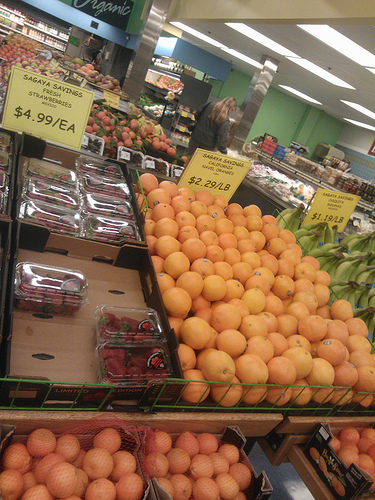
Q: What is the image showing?
A: It is showing a store.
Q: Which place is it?
A: It is a store.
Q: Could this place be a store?
A: Yes, it is a store.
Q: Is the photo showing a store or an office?
A: It is showing a store.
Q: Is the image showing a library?
A: No, the picture is showing a store.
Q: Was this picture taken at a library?
A: No, the picture was taken in a store.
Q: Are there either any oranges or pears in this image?
A: Yes, there are oranges.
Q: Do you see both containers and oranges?
A: Yes, there are both oranges and a container.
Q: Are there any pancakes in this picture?
A: No, there are no pancakes.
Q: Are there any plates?
A: No, there are no plates.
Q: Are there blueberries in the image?
A: No, there are no blueberries.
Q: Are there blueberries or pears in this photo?
A: No, there are no blueberries or pears.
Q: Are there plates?
A: No, there are no plates.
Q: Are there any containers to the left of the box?
A: Yes, there is a container to the left of the box.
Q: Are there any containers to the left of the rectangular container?
A: Yes, there is a container to the left of the box.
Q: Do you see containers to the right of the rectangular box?
A: No, the container is to the left of the box.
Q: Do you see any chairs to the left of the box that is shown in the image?
A: No, there is a container to the left of the box.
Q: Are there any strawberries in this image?
A: Yes, there are strawberries.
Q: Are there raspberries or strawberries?
A: Yes, there are strawberries.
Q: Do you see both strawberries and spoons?
A: No, there are strawberries but no spoons.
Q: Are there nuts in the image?
A: No, there are no nuts.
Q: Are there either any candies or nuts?
A: No, there are no nuts or candies.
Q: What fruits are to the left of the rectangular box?
A: The fruits are strawberries.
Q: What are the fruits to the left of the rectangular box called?
A: The fruits are strawberries.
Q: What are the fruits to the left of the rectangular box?
A: The fruits are strawberries.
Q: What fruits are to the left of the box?
A: The fruits are strawberries.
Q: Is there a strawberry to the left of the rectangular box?
A: Yes, there are strawberries to the left of the box.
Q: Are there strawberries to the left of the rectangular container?
A: Yes, there are strawberries to the left of the box.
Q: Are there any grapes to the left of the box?
A: No, there are strawberries to the left of the box.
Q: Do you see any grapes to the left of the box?
A: No, there are strawberries to the left of the box.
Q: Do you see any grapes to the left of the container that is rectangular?
A: No, there are strawberries to the left of the box.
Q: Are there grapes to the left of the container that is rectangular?
A: No, there are strawberries to the left of the box.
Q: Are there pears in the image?
A: No, there are no pears.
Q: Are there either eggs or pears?
A: No, there are no pears or eggs.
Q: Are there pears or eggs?
A: No, there are no pears or eggs.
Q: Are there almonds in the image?
A: No, there are no almonds.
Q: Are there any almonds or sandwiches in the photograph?
A: No, there are no almonds or sandwiches.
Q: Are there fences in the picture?
A: No, there are no fences.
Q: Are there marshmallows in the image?
A: No, there are no marshmallows.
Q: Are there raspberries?
A: No, there are no raspberries.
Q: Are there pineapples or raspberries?
A: No, there are no raspberries or pineapples.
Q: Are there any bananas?
A: Yes, there is a banana.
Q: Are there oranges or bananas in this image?
A: Yes, there is a banana.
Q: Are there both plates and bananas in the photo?
A: No, there is a banana but no plates.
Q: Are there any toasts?
A: No, there are no toasts.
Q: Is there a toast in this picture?
A: No, there are no toasts.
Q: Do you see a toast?
A: No, there are no toasts.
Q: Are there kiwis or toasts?
A: No, there are no toasts or kiwis.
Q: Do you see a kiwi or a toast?
A: No, there are no toasts or kiwis.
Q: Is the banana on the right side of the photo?
A: Yes, the banana is on the right of the image.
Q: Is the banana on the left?
A: No, the banana is on the right of the image.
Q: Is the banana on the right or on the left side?
A: The banana is on the right of the image.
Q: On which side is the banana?
A: The banana is on the right of the image.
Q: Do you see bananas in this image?
A: Yes, there is a banana.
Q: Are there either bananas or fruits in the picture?
A: Yes, there is a banana.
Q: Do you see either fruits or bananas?
A: Yes, there is a banana.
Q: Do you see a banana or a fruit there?
A: Yes, there is a banana.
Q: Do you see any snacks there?
A: No, there are no snacks.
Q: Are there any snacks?
A: No, there are no snacks.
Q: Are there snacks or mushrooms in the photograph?
A: No, there are no snacks or mushrooms.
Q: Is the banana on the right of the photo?
A: Yes, the banana is on the right of the image.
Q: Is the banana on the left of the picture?
A: No, the banana is on the right of the image.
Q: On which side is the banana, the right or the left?
A: The banana is on the right of the image.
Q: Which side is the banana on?
A: The banana is on the right of the image.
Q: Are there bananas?
A: Yes, there is a banana.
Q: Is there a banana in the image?
A: Yes, there is a banana.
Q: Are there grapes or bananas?
A: Yes, there is a banana.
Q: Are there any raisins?
A: No, there are no raisins.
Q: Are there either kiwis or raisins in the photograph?
A: No, there are no raisins or kiwis.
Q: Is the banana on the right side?
A: Yes, the banana is on the right of the image.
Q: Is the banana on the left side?
A: No, the banana is on the right of the image.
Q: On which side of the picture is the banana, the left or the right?
A: The banana is on the right of the image.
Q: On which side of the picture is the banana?
A: The banana is on the right of the image.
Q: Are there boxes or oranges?
A: Yes, there are oranges.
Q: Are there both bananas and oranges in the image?
A: Yes, there are both oranges and a banana.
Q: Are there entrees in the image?
A: No, there are no entrees.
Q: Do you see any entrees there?
A: No, there are no entrees.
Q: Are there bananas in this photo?
A: Yes, there are bananas.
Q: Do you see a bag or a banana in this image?
A: Yes, there are bananas.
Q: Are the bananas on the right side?
A: Yes, the bananas are on the right of the image.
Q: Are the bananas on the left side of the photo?
A: No, the bananas are on the right of the image.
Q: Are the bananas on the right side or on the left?
A: The bananas are on the right of the image.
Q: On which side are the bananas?
A: The bananas are on the right of the image.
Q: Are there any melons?
A: No, there are no melons.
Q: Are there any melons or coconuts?
A: No, there are no melons or coconuts.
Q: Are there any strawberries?
A: Yes, there are strawberries.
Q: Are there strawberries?
A: Yes, there are strawberries.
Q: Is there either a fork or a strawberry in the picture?
A: Yes, there are strawberries.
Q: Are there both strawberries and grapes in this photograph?
A: No, there are strawberries but no grapes.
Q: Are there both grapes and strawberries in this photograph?
A: No, there are strawberries but no grapes.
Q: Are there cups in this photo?
A: No, there are no cups.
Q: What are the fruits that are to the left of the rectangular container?
A: The fruits are strawberries.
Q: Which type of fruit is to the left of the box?
A: The fruits are strawberries.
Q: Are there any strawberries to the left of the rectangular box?
A: Yes, there are strawberries to the left of the box.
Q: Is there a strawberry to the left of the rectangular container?
A: Yes, there are strawberries to the left of the box.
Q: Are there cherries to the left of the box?
A: No, there are strawberries to the left of the box.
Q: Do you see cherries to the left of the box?
A: No, there are strawberries to the left of the box.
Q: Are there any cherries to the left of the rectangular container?
A: No, there are strawberries to the left of the box.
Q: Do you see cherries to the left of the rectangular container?
A: No, there are strawberries to the left of the box.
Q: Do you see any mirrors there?
A: No, there are no mirrors.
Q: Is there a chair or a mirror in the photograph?
A: No, there are no mirrors or chairs.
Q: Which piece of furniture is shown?
A: The piece of furniture is a shelf.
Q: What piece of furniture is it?
A: The piece of furniture is a shelf.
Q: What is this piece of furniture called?
A: This is a shelf.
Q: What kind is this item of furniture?
A: This is a shelf.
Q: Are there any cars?
A: No, there are no cars.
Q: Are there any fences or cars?
A: No, there are no cars or fences.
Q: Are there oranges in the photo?
A: Yes, there are oranges.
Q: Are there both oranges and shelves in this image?
A: Yes, there are both oranges and a shelf.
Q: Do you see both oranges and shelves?
A: Yes, there are both oranges and a shelf.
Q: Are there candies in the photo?
A: No, there are no candies.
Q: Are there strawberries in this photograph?
A: Yes, there are strawberries.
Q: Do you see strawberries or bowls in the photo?
A: Yes, there are strawberries.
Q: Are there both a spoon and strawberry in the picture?
A: No, there are strawberries but no spoons.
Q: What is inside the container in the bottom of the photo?
A: The strawberries are inside the container.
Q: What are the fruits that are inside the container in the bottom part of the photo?
A: The fruits are strawberries.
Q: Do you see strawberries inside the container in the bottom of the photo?
A: Yes, there are strawberries inside the container.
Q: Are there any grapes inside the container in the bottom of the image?
A: No, there are strawberries inside the container.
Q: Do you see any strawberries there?
A: Yes, there are strawberries.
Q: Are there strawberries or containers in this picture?
A: Yes, there are strawberries.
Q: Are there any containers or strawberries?
A: Yes, there are strawberries.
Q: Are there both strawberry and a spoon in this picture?
A: No, there are strawberries but no spoons.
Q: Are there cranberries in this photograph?
A: No, there are no cranberries.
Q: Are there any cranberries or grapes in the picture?
A: No, there are no cranberries or grapes.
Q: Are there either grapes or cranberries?
A: No, there are no cranberries or grapes.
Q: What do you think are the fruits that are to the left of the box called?
A: The fruits are strawberries.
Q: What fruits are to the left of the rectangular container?
A: The fruits are strawberries.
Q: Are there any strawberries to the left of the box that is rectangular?
A: Yes, there are strawberries to the left of the box.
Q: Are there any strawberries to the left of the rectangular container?
A: Yes, there are strawberries to the left of the box.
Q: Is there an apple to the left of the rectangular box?
A: No, there are strawberries to the left of the box.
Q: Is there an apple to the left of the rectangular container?
A: No, there are strawberries to the left of the box.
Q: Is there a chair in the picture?
A: No, there are no chairs.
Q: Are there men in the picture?
A: No, there are no men.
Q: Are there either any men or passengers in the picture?
A: No, there are no men or passengers.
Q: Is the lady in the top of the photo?
A: Yes, the lady is in the top of the image.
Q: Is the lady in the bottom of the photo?
A: No, the lady is in the top of the image.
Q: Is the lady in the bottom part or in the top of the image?
A: The lady is in the top of the image.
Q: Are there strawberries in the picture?
A: Yes, there are strawberries.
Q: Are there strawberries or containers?
A: Yes, there are strawberries.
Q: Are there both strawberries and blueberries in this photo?
A: No, there are strawberries but no blueberries.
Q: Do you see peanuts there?
A: No, there are no peanuts.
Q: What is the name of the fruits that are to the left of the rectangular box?
A: The fruits are strawberries.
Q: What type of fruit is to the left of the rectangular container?
A: The fruits are strawberries.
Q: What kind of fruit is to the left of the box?
A: The fruits are strawberries.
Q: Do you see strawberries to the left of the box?
A: Yes, there are strawberries to the left of the box.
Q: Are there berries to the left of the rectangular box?
A: No, there are strawberries to the left of the box.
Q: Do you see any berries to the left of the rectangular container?
A: No, there are strawberries to the left of the box.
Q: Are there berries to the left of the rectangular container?
A: No, there are strawberries to the left of the box.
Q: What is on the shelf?
A: The strawberries are on the shelf.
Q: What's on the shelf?
A: The strawberries are on the shelf.